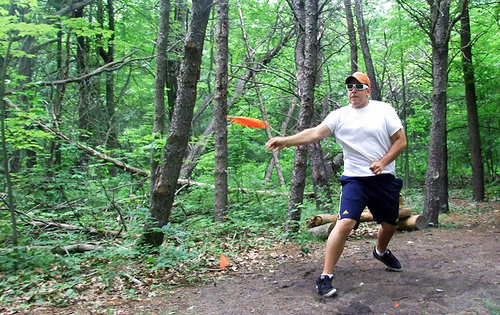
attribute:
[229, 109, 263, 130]
frisbee — orange, small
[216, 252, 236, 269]
flag — orange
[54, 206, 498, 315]
ground — dirt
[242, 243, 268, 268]
leaves — green, small, gold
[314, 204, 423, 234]
logs — stacked, wooden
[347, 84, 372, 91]
sunglasses — white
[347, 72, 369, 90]
hat — orange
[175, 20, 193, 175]
trunk — large, black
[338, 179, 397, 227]
shorts — blue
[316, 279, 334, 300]
sneakers — black, white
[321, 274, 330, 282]
sock — white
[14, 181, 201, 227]
shrubs — green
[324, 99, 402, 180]
shirt — white